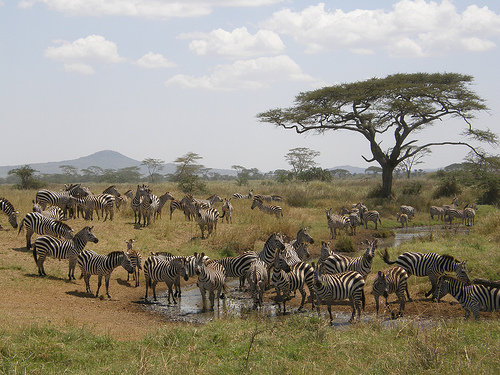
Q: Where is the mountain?
A: Background.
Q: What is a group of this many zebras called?
A: A herd.